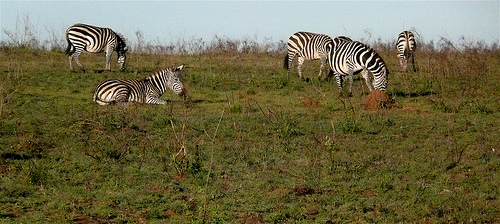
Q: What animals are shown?
A: Zebras.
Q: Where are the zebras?
A: In the wild.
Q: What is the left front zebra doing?
A: Lying down.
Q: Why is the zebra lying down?
A: To rest.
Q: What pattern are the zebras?
A: Striped.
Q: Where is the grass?
A: Around the zebras.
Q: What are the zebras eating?
A: Grass.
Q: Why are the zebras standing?
A: To eat.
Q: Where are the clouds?
A: In the sky.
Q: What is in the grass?
A: Animals.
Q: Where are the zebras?
A: On a large pasture of grass.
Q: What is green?
A: The grass.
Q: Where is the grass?
A: On the pasture.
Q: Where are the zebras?
A: On a pasture.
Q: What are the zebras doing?
A: Eating.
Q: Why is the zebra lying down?
A: It's relaxing.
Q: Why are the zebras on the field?
A: They are eating.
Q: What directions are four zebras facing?
A: The right.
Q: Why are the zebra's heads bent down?
A: Eating.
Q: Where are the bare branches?
A: Forefront in grass.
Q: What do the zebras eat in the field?
A: Grass small shrubs.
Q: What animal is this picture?
A: Zebra.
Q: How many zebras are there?
A: Five.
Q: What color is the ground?
A: Green.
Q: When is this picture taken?
A: During the day.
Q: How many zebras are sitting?
A: One.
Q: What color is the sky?
A: Blue.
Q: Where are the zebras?
A: In a field.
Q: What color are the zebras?
A: White and black.